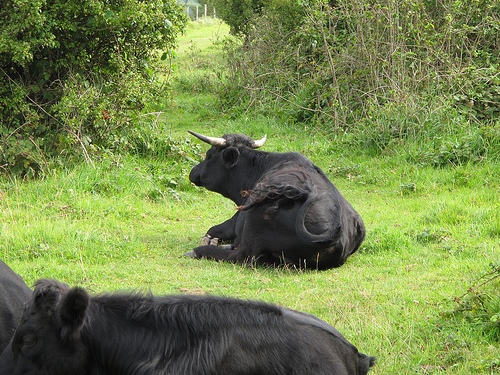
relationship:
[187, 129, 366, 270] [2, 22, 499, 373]
bull on ground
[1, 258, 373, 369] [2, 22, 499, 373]
bull lying ground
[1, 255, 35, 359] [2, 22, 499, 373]
bull lying ground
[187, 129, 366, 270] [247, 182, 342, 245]
bull has tail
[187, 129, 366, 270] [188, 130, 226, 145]
bull has horn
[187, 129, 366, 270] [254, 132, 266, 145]
bull has horn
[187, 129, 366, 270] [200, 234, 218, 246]
bull has hoof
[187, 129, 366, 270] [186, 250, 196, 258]
bull has hoof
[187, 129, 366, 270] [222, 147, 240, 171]
bull has ear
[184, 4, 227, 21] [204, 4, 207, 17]
fence has post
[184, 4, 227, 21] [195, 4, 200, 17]
fence has post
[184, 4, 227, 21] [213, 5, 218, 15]
fence has post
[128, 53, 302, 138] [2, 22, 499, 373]
passage on ground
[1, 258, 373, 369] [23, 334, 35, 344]
bull has eye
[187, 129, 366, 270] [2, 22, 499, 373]
bull sitting on ground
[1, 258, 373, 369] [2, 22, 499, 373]
bull sitting on ground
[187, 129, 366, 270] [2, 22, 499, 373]
bull sitting in ground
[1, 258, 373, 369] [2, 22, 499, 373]
bull sitting in ground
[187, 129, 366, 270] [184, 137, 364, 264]
bull has fur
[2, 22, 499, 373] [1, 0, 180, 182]
ground has brush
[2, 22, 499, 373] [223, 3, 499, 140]
ground has brush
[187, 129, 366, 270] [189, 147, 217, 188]
bull has face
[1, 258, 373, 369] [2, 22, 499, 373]
bull on ground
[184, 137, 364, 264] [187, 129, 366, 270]
fur on bull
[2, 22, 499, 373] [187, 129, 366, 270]
ground under bull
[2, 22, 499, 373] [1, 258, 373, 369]
ground under bull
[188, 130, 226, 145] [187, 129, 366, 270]
horn on bull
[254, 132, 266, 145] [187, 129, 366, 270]
horn on bull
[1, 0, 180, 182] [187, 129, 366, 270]
brush near bull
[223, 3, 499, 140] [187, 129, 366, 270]
brush near bull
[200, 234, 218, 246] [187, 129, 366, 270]
hoof on bull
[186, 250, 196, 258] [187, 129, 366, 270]
hoof on bull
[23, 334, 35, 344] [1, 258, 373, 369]
eye on bull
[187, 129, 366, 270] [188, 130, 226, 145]
bull has left horn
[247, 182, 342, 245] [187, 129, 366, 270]
tail on bull